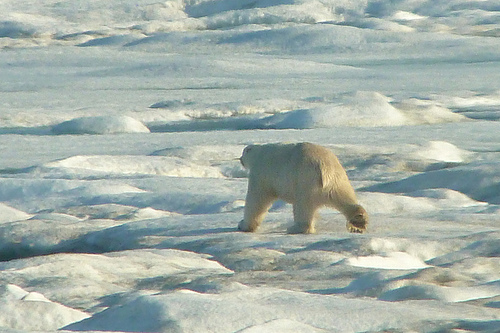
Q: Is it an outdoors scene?
A: Yes, it is outdoors.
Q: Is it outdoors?
A: Yes, it is outdoors.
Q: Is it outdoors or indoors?
A: It is outdoors.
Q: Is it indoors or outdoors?
A: It is outdoors.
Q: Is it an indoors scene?
A: No, it is outdoors.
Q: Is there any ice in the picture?
A: Yes, there is ice.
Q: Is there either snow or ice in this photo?
A: Yes, there is ice.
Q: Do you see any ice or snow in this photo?
A: Yes, there is ice.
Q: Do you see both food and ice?
A: No, there is ice but no food.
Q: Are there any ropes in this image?
A: No, there are no ropes.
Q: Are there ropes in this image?
A: No, there are no ropes.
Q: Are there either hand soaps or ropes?
A: No, there are no ropes or hand soaps.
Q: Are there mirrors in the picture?
A: No, there are no mirrors.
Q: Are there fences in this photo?
A: No, there are no fences.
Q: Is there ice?
A: Yes, there is ice.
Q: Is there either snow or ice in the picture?
A: Yes, there is ice.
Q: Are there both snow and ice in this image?
A: Yes, there are both ice and snow.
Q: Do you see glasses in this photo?
A: No, there are no glasses.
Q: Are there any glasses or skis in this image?
A: No, there are no glasses or skis.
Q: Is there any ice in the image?
A: Yes, there is ice.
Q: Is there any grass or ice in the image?
A: Yes, there is ice.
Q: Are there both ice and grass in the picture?
A: No, there is ice but no grass.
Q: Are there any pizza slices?
A: No, there are no pizza slices.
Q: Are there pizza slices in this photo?
A: No, there are no pizza slices.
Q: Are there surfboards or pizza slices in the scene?
A: No, there are no pizza slices or surfboards.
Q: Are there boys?
A: No, there are no boys.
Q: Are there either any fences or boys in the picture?
A: No, there are no boys or fences.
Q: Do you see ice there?
A: Yes, there is ice.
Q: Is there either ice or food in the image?
A: Yes, there is ice.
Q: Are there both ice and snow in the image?
A: Yes, there are both ice and snow.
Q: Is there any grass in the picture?
A: No, there is no grass.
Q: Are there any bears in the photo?
A: Yes, there is a bear.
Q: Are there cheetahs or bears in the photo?
A: Yes, there is a bear.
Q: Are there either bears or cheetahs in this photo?
A: Yes, there is a bear.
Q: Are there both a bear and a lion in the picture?
A: No, there is a bear but no lions.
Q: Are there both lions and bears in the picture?
A: No, there is a bear but no lions.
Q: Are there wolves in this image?
A: No, there are no wolves.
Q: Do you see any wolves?
A: No, there are no wolves.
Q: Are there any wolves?
A: No, there are no wolves.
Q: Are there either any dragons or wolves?
A: No, there are no wolves or dragons.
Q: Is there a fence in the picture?
A: No, there are no fences.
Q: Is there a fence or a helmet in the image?
A: No, there are no fences or helmets.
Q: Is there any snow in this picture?
A: Yes, there is snow.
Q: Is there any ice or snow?
A: Yes, there is snow.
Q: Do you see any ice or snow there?
A: Yes, there is snow.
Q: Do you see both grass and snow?
A: No, there is snow but no grass.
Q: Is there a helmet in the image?
A: No, there are no helmets.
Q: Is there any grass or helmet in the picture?
A: No, there are no helmets or grass.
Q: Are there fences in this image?
A: No, there are no fences.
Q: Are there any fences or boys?
A: No, there are no fences or boys.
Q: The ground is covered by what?
A: The ground is covered by the snow.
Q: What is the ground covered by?
A: The ground is covered by the snow.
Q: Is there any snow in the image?
A: Yes, there is snow.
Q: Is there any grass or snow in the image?
A: Yes, there is snow.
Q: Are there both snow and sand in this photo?
A: No, there is snow but no sand.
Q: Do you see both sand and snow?
A: No, there is snow but no sand.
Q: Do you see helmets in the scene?
A: No, there are no helmets.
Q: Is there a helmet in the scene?
A: No, there are no helmets.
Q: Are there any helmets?
A: No, there are no helmets.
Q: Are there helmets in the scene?
A: No, there are no helmets.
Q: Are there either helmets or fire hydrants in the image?
A: No, there are no helmets or fire hydrants.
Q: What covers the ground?
A: The snow covers the ground.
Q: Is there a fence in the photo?
A: No, there are no fences.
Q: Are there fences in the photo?
A: No, there are no fences.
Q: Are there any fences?
A: No, there are no fences.